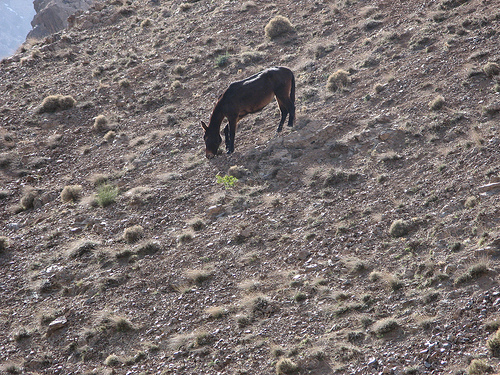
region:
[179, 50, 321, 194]
This is a donkey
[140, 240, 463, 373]
Section of a field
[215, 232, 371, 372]
Section of a field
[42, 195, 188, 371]
Section of a field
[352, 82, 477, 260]
Section of a field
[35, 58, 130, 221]
Section of a field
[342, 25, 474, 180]
Section of a field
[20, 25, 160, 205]
Section of a field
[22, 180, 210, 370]
Section of a field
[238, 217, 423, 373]
Section of a field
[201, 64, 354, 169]
horse on the hill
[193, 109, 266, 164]
the horse is grazing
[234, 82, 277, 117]
the horse is thin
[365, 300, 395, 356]
bushes on the hill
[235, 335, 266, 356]
stones on the dirt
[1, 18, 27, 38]
the sky is clear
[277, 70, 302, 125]
tail of the horse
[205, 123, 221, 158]
head of the horse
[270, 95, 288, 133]
leg of the horse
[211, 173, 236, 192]
plant on the hill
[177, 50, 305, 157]
A black donkey grazing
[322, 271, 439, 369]
A rocky desert ground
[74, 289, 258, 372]
A rocky desert ground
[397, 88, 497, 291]
A rocky desert ground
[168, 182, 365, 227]
A rocky desert ground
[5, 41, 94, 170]
A rocky desert ground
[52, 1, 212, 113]
A rocky desert ground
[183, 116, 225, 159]
head of a donkey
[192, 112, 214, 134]
ear of a donkey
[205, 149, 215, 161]
mouth of a donkey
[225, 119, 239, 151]
leg of a donkey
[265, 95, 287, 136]
leg of a donkey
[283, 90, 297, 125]
leg of a donkey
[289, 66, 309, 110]
tail of a donkey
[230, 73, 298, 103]
body of a donkey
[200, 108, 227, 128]
neck of a donkey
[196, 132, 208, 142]
eye of a donkey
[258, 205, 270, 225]
Black dog in the ground eating.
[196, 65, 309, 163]
A donkey grazing a scruffy hilltop.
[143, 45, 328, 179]
A donkey standing on sparse slope.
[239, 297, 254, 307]
brown grass on the dirt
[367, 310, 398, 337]
brown grass on the dirt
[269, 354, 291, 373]
brown grass on the dirt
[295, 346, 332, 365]
brown grass on the dirt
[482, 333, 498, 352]
brown grass on the dirt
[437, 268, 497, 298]
brown grass on the dirt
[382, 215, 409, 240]
brown grass on the dirt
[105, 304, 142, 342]
brown grass on the dirt